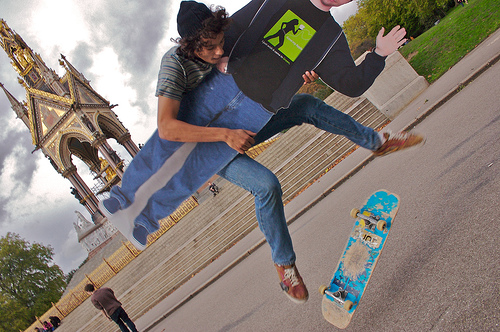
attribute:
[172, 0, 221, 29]
cap — black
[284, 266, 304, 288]
lace — white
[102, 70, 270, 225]
jeans — blue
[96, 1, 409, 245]
cutout — cardboard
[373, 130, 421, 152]
shoes — brown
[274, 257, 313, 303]
shoes — brown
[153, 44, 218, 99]
shirt — striped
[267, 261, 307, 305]
shoe — brown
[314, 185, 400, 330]
skateboard — blue, wooden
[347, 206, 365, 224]
wheel — small, yellow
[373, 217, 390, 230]
wheel — yellow, small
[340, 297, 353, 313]
wheel — small, yellow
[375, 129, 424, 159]
shoe — red, white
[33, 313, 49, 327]
post — tall, yellow, metal, fence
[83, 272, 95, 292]
post — fence, metal, yellow, tall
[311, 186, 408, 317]
skateboard — blue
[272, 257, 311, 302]
shoe — brown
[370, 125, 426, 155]
shoe — brown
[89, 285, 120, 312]
shirt — brown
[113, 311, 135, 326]
pants — black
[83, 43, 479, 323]
cement — gray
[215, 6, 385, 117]
shirt — black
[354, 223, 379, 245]
trim — gray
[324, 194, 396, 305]
skateboard — blue base 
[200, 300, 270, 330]
train tracks — set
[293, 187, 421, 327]
skateboard — blue 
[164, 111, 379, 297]
jeans — blue 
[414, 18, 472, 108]
leaf — green 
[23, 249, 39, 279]
leaf — green 